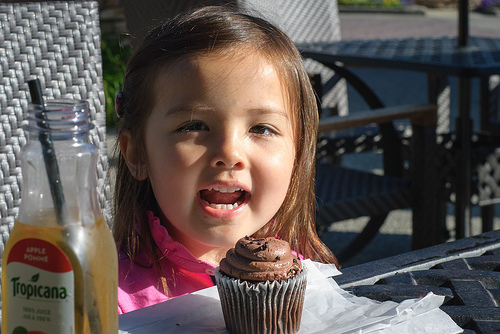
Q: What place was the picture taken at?
A: It was taken at the patio.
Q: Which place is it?
A: It is a patio.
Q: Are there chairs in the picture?
A: Yes, there is a chair.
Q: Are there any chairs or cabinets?
A: Yes, there is a chair.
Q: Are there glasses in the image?
A: No, there are no glasses.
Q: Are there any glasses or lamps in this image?
A: No, there are no glasses or lamps.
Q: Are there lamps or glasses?
A: No, there are no glasses or lamps.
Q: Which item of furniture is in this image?
A: The piece of furniture is a chair.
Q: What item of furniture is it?
A: The piece of furniture is a chair.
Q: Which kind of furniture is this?
A: This is a chair.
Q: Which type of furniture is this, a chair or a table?
A: This is a chair.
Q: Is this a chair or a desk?
A: This is a chair.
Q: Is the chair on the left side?
A: Yes, the chair is on the left of the image.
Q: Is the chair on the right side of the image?
A: No, the chair is on the left of the image.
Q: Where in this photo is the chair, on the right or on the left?
A: The chair is on the left of the image.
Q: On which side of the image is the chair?
A: The chair is on the left of the image.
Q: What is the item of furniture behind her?
A: The piece of furniture is a chair.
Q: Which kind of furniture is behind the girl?
A: The piece of furniture is a chair.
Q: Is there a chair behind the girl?
A: Yes, there is a chair behind the girl.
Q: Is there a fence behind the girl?
A: No, there is a chair behind the girl.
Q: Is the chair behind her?
A: Yes, the chair is behind the girl.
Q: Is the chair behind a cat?
A: No, the chair is behind the girl.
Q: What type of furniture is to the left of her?
A: The piece of furniture is a chair.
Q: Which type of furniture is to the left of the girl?
A: The piece of furniture is a chair.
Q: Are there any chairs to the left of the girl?
A: Yes, there is a chair to the left of the girl.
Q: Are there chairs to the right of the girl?
A: No, the chair is to the left of the girl.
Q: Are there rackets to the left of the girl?
A: No, there is a chair to the left of the girl.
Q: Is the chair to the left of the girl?
A: Yes, the chair is to the left of the girl.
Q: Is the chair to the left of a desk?
A: No, the chair is to the left of the girl.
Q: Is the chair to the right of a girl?
A: No, the chair is to the left of a girl.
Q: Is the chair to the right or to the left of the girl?
A: The chair is to the left of the girl.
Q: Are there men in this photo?
A: No, there are no men.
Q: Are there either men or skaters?
A: No, there are no men or skaters.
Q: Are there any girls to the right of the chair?
A: Yes, there is a girl to the right of the chair.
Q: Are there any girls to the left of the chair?
A: No, the girl is to the right of the chair.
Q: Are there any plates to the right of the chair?
A: No, there is a girl to the right of the chair.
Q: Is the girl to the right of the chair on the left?
A: Yes, the girl is to the right of the chair.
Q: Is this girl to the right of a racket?
A: No, the girl is to the right of the chair.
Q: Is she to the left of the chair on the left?
A: No, the girl is to the right of the chair.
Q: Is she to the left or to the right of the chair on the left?
A: The girl is to the right of the chair.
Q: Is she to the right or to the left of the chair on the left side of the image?
A: The girl is to the right of the chair.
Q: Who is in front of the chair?
A: The girl is in front of the chair.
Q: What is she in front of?
A: The girl is in front of the chair.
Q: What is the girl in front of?
A: The girl is in front of the chair.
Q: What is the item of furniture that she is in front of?
A: The piece of furniture is a chair.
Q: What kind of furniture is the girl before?
A: The girl is in front of the chair.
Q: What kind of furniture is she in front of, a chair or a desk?
A: The girl is in front of a chair.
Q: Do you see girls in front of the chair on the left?
A: Yes, there is a girl in front of the chair.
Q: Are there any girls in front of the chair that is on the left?
A: Yes, there is a girl in front of the chair.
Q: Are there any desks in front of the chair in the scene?
A: No, there is a girl in front of the chair.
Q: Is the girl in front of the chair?
A: Yes, the girl is in front of the chair.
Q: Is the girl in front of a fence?
A: No, the girl is in front of the chair.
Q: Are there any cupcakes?
A: Yes, there is a cupcake.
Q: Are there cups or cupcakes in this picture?
A: Yes, there is a cupcake.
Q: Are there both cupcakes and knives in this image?
A: No, there is a cupcake but no knives.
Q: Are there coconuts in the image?
A: No, there are no coconuts.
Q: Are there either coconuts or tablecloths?
A: No, there are no coconuts or tablecloths.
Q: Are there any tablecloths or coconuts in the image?
A: No, there are no coconuts or tablecloths.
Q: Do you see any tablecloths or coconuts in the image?
A: No, there are no coconuts or tablecloths.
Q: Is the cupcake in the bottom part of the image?
A: Yes, the cupcake is in the bottom of the image.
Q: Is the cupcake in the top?
A: No, the cupcake is in the bottom of the image.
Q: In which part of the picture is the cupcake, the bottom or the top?
A: The cupcake is in the bottom of the image.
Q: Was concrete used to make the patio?
A: Yes, the patio is made of concrete.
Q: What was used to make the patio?
A: The patio is made of concrete.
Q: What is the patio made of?
A: The patio is made of concrete.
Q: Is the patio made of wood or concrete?
A: The patio is made of concrete.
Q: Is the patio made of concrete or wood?
A: The patio is made of concrete.